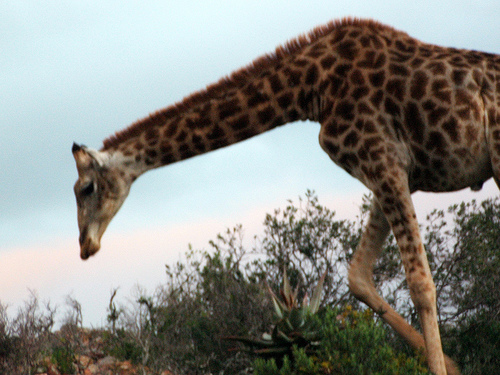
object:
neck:
[105, 29, 323, 178]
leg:
[373, 167, 448, 375]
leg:
[348, 192, 462, 374]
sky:
[0, 0, 500, 337]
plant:
[148, 191, 366, 374]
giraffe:
[72, 17, 500, 375]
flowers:
[334, 313, 344, 321]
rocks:
[93, 357, 124, 375]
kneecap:
[350, 280, 367, 299]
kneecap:
[410, 290, 429, 310]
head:
[71, 141, 134, 262]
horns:
[71, 141, 94, 169]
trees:
[422, 192, 500, 374]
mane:
[102, 15, 389, 151]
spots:
[409, 69, 431, 102]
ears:
[71, 141, 101, 176]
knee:
[348, 268, 379, 306]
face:
[74, 170, 116, 261]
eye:
[79, 180, 95, 198]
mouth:
[84, 236, 92, 258]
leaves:
[290, 219, 321, 245]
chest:
[315, 118, 367, 190]